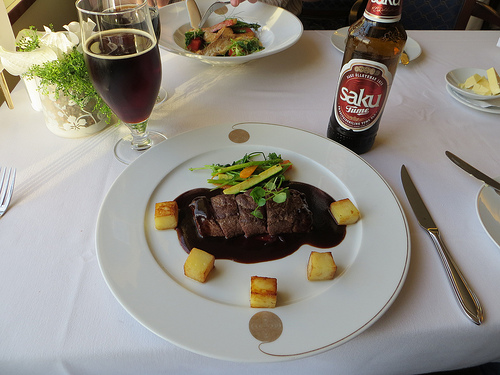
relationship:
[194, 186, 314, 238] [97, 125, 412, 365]
steak on plate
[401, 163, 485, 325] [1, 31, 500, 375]
knife on table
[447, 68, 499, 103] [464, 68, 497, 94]
plate of butter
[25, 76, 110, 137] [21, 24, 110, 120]
vase with green plant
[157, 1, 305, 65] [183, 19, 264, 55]
bowl of chicken salad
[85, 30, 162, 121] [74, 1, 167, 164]
drink in wine glass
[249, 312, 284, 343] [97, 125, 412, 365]
art on plate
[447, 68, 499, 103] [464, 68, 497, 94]
plate with butter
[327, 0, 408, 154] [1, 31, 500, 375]
saku beer bottle on table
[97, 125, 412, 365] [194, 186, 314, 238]
plate of steak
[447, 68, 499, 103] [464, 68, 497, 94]
plate filled with butter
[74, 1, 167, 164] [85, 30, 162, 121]
wine glass with drink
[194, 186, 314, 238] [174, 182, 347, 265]
steak with a sauce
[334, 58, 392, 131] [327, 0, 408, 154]
saku lable on saku beer bottle